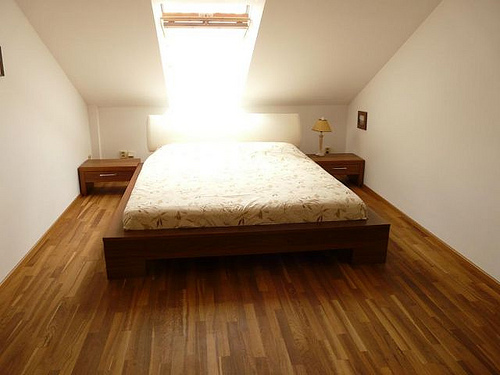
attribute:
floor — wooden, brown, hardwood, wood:
[2, 174, 500, 374]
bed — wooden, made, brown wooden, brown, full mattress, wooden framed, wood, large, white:
[104, 113, 389, 283]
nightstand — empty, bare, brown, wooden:
[77, 157, 137, 196]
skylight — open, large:
[154, 3, 264, 103]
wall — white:
[2, 1, 95, 300]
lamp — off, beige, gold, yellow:
[313, 117, 334, 157]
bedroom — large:
[1, 2, 499, 374]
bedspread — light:
[124, 139, 368, 227]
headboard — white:
[147, 112, 302, 145]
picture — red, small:
[355, 109, 371, 134]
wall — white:
[344, 0, 500, 281]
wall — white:
[88, 101, 349, 159]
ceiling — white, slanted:
[18, 1, 441, 110]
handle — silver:
[98, 171, 115, 178]